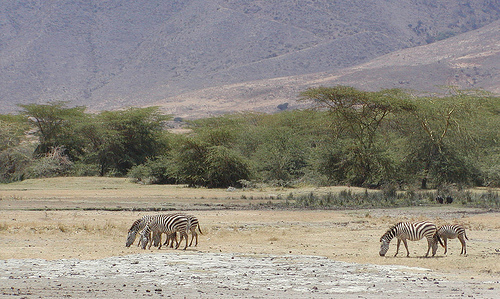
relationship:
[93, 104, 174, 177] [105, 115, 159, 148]
tree with thorns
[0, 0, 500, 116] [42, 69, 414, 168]
mountains behind trees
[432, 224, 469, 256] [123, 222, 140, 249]
zebra with head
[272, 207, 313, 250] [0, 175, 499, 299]
grass on barren land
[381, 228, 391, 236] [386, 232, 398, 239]
mane on neck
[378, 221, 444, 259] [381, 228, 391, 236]
zebra with mane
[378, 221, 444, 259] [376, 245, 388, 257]
zebra with muzzle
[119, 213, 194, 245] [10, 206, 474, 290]
zebra in a field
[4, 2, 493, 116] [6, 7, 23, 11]
mountains with hills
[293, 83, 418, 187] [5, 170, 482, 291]
tree towards back of field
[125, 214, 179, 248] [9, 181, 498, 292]
zebra graze in field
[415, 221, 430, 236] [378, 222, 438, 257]
stripes on zebra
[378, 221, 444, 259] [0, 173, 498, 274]
zebra eating grass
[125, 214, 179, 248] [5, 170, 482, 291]
zebra on field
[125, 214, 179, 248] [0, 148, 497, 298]
zebra grazing on plain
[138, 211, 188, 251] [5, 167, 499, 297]
zebra grazing on barren land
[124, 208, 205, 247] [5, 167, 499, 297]
zebra grazing on barren land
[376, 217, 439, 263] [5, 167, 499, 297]
zebra grazing on barren land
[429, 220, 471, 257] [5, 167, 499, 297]
zebra grazing on barren land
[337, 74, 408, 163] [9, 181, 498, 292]
tree at edge of field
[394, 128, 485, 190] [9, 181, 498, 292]
tree at edge of field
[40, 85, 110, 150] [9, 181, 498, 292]
tree at edge of field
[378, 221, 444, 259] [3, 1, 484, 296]
zebra in photo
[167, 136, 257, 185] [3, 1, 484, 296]
tree in photo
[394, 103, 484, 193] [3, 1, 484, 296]
tree in photo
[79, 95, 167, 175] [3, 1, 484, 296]
tree in photo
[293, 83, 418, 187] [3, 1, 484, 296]
tree in photo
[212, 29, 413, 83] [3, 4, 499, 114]
hill in background